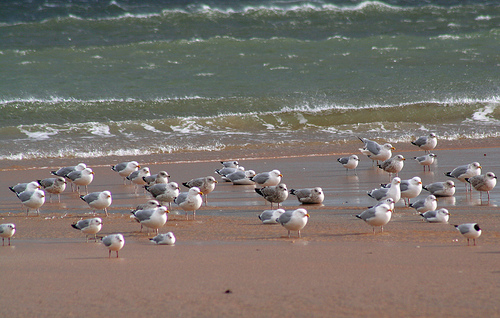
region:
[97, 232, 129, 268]
gray and white bird on the beach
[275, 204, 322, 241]
gray and white bird on the beach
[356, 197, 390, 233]
gray and white bird on the beach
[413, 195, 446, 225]
gray and white bird on the beach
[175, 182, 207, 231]
gray and white bird on the beach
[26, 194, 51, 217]
gray and white bird on the beach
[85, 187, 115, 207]
gray and white bird on the beach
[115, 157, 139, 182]
gray and white bird on the beach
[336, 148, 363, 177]
gray and white bird on the beach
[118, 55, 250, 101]
body of water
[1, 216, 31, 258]
The bird is grounded.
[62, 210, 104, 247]
The bird is grounded.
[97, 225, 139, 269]
The bird is grounded.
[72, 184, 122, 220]
The bird is grounded.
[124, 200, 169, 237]
The bird is grounded.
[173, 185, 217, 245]
The bird is grounded.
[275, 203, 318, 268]
The bird is grounded.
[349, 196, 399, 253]
The bird is grounded.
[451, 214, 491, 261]
The bird is grounded.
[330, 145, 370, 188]
The bird is grounded.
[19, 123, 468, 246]
birds at the shore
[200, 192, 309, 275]
the sand is wet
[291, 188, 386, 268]
the sand is wet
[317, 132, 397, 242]
the sand is wet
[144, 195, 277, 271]
the sand is wet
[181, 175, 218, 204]
gray and white bird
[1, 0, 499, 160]
part of the ocean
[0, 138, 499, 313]
sand on the beach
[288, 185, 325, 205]
gray and white bird is lying down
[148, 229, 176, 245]
small gray and white bird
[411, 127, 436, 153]
large white and gray bird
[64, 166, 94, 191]
white and grey bird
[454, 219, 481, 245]
gray and white bird with black face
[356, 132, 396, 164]
gray and white sea bird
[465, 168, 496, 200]
gray and white bird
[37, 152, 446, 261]
seagulls on a beach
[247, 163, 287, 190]
a white and grey seagull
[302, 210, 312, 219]
the orange beak of a seagull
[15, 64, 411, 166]
waves arriving on the shore of a beach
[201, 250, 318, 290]
sand on a beach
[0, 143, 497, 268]
a flock of seagulls standing on the ground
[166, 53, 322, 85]
choppiness on the water's surface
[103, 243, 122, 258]
the legs of a bird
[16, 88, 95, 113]
white water spray from a wave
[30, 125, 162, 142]
white foam on a wave